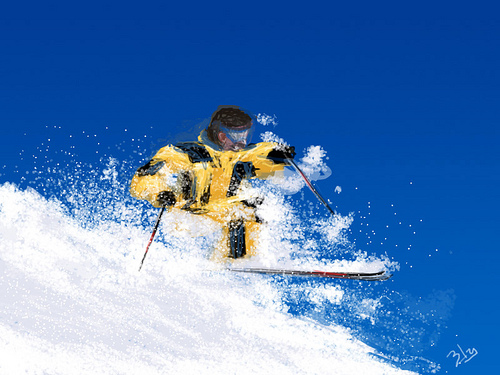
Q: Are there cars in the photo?
A: No, there are no cars.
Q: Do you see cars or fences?
A: No, there are no cars or fences.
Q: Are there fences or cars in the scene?
A: No, there are no cars or fences.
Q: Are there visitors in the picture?
A: No, there are no visitors.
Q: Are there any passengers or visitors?
A: No, there are no visitors or passengers.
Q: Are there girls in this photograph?
A: No, there are no girls.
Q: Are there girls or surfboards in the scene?
A: No, there are no girls or surfboards.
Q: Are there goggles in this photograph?
A: Yes, there are goggles.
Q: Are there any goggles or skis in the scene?
A: Yes, there are goggles.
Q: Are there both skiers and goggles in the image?
A: Yes, there are both goggles and a skier.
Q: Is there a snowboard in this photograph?
A: No, there are no snowboards.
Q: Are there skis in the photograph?
A: Yes, there are skis.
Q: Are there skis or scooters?
A: Yes, there are skis.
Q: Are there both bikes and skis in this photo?
A: No, there are skis but no bikes.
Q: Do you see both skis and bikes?
A: No, there are skis but no bikes.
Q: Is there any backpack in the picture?
A: No, there are no backpacks.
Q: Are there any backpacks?
A: No, there are no backpacks.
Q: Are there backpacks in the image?
A: No, there are no backpacks.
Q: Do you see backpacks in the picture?
A: No, there are no backpacks.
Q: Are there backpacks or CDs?
A: No, there are no backpacks or cds.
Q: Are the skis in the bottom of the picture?
A: Yes, the skis are in the bottom of the image.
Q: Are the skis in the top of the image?
A: No, the skis are in the bottom of the image.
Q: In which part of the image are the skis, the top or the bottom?
A: The skis are in the bottom of the image.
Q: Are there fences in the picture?
A: No, there are no fences.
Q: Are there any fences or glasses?
A: No, there are no fences or glasses.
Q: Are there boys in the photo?
A: No, there are no boys.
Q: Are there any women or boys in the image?
A: No, there are no boys or women.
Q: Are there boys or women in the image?
A: No, there are no boys or women.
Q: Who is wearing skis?
A: The man is wearing skis.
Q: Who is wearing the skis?
A: The man is wearing skis.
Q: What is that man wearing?
A: The man is wearing skis.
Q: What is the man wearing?
A: The man is wearing skis.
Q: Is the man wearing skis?
A: Yes, the man is wearing skis.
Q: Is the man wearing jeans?
A: No, the man is wearing skis.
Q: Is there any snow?
A: Yes, there is snow.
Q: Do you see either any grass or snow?
A: Yes, there is snow.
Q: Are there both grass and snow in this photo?
A: No, there is snow but no grass.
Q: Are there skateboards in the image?
A: No, there are no skateboards.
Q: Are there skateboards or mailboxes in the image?
A: No, there are no skateboards or mailboxes.